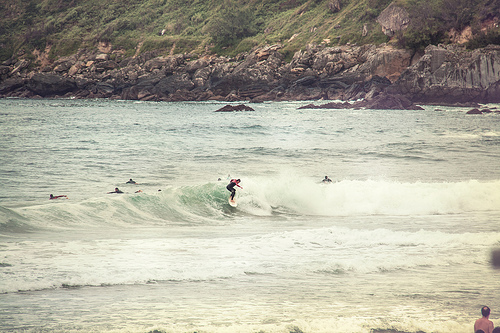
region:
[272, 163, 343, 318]
the water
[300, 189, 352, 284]
the water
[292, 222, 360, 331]
the water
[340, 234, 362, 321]
the water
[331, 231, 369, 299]
the water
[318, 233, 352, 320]
the water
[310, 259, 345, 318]
the water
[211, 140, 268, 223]
a person in water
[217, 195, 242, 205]
legs of the person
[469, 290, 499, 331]
a women seeing the water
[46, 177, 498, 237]
a water rising view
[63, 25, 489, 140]
a beautiful view of rocks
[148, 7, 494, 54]
a beautiful view of grass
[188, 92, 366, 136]
a small rock inside the water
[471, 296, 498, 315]
head of the person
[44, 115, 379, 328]
beautiful view of water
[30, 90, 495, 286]
group of people skating in water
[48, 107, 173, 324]
the water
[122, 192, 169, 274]
the water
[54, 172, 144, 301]
the water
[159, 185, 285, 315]
the water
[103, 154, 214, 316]
the water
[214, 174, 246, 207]
A man riding a wave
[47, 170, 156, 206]
People paddle out to sea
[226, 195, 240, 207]
A white surfboard.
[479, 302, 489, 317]
A balding man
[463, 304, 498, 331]
A man on the beach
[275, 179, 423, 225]
The waves crashing down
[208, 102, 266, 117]
Rocks in the water.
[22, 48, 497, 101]
Rocks on the beach.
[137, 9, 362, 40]
Grass on the hillside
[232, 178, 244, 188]
The pink on the shirt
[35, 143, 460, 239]
People enjoying the beach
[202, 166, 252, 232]
Surfer catching a wave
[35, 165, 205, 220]
People swimming in the water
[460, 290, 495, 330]
Person enjoying the beach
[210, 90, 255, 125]
Rocks above the waterline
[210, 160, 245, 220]
Person riding a surfboard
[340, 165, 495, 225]
Wave coming in to the beach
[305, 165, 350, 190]
Person out in the ocean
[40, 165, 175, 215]
People swimming together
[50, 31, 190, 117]
Coastline at the beach